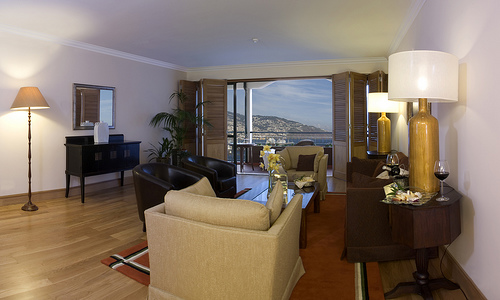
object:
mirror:
[71, 83, 118, 129]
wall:
[0, 30, 191, 199]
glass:
[431, 159, 452, 203]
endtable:
[384, 185, 463, 299]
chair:
[131, 161, 207, 233]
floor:
[0, 175, 462, 299]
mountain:
[225, 112, 332, 140]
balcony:
[229, 157, 337, 175]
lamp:
[386, 50, 459, 199]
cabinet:
[64, 132, 141, 202]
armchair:
[141, 176, 305, 300]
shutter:
[176, 79, 227, 163]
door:
[230, 81, 237, 166]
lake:
[232, 137, 331, 147]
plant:
[144, 90, 218, 162]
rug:
[103, 193, 382, 298]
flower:
[259, 145, 281, 174]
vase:
[268, 162, 288, 203]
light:
[7, 87, 48, 212]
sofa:
[343, 153, 438, 265]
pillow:
[296, 154, 316, 171]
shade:
[438, 55, 466, 190]